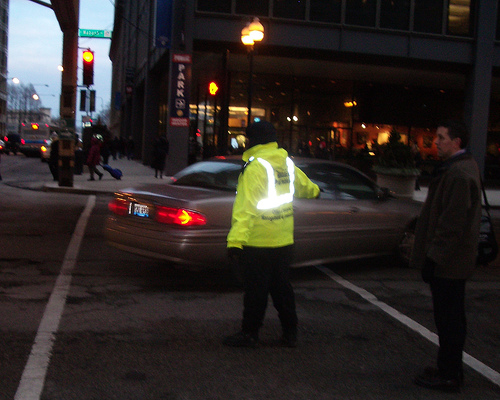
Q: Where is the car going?
A: To the right.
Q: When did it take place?
A: At night.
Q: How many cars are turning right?
A: One.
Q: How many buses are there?
A: One.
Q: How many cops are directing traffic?
A: One.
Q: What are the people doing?
A: Crossing the street.